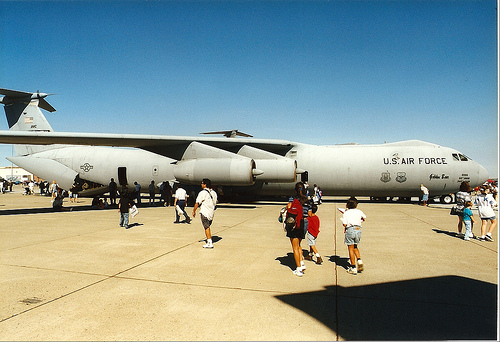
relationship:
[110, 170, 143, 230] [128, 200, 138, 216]
people carrying bag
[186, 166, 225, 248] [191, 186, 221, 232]
man dressed in attire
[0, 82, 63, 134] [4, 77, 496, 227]
wing on airplane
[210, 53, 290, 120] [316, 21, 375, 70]
clouds in sky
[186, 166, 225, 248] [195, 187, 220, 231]
man in a attire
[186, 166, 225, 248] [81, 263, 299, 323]
man walking on tarmac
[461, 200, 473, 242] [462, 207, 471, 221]
girl wearing shirt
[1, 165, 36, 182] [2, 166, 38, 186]
building has wall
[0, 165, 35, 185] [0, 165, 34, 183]
wall on building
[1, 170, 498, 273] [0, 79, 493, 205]
people walking around aircraft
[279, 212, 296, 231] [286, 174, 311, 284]
purse on woman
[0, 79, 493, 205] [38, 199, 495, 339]
aircraft on tarmac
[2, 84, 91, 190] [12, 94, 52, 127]
tail on plane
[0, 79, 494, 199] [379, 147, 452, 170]
aircraft belonging to air force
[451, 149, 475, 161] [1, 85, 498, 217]
window for plane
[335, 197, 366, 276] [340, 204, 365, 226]
child in white shirt white shirt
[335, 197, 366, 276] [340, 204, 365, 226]
child in blue jean shorts white shirt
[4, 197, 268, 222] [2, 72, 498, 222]
shadow of a plane